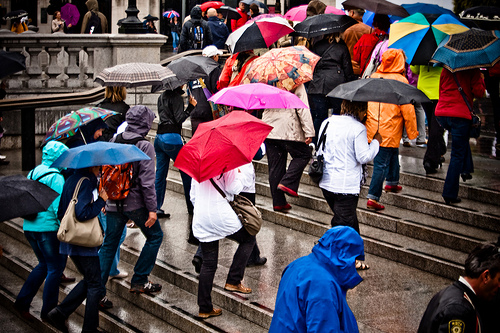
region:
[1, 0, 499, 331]
a very large crowd walks up very wet steps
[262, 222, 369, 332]
a bright blue enclosing hood on a bright blue rain jacket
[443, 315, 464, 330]
an official insignia on the shoulder of a black jacket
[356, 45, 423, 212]
flat bright red shoes worn with bright orange jacket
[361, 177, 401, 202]
cuffs upon the levis above the flat red shoes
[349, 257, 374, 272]
the ½-bare foot of a woman wearing sandals in the rain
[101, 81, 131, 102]
a bit of blonde hair in a sea of dark & brightly covered heads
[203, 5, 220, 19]
man without hair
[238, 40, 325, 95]
a patterned reddish umbrella among mostly solid colors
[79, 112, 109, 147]
a person's light face in a dark hood, looking down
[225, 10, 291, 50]
white, black and red umbrella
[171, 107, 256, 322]
person carrying red umbrella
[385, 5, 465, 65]
black, green, yellow and blue umbrella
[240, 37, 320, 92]
abstract print umbrella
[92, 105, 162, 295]
person carrying a red backpack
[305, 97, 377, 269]
woman carrying a black handbag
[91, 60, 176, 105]
tan and black plaid umbrella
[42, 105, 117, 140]
colorful abstract pattern umbrella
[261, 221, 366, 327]
person wearing a blue hooded jacket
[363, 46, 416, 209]
woman in an orange raincoat and red shoes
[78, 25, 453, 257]
It is a rainy day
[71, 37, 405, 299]
The people are walking up stairs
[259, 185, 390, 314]
This jacket is blue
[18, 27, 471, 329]
The stairs are made of stone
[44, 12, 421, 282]
The stairs are grey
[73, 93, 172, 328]
This person is wearing jeans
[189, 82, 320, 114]
This umbrella is pink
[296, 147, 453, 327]
There are 4 steps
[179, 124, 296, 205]
This umbrella is red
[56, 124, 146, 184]
This umbrella is blue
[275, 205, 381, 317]
the wind breaker is blue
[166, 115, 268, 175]
the umbrella is red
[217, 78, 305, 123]
the umbrella is pink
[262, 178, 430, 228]
the shoes are red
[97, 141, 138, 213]
the bag is red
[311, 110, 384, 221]
the jacket is white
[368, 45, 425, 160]
the rain coat is orange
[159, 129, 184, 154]
the bag is blue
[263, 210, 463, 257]
the stairs is wet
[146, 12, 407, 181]
people are going up the stairs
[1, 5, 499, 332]
the photo is clear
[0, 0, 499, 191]
people carrying umbrellas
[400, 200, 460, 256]
they are climbing staircase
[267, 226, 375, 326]
this is a man wearing a jacket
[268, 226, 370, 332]
the jacket is blue is color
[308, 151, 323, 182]
the woman is carrying a black bag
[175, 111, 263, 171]
this is a red umbrella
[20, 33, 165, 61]
the stand is made of cement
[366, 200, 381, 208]
the woman is wearing red shoes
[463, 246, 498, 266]
the man is having grey hair